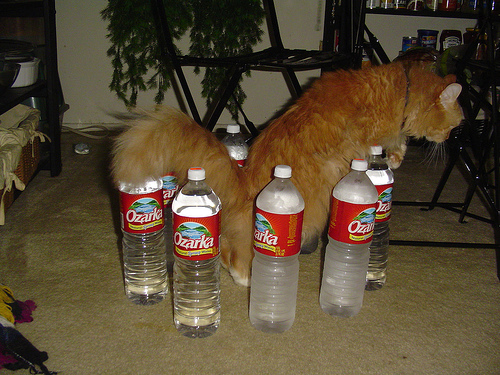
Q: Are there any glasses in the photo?
A: No, there are no glasses.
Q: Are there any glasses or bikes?
A: No, there are no glasses or bikes.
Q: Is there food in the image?
A: Yes, there is food.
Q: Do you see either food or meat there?
A: Yes, there is food.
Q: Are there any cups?
A: No, there are no cups.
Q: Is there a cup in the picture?
A: No, there are no cups.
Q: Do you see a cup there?
A: No, there are no cups.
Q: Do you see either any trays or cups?
A: No, there are no cups or trays.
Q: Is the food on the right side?
A: Yes, the food is on the right of the image.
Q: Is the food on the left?
A: No, the food is on the right of the image.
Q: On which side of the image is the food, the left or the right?
A: The food is on the right of the image.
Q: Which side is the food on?
A: The food is on the right of the image.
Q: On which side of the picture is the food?
A: The food is on the right of the image.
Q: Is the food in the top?
A: Yes, the food is in the top of the image.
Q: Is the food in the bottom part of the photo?
A: No, the food is in the top of the image.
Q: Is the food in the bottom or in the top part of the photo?
A: The food is in the top of the image.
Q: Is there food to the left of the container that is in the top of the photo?
A: Yes, there is food to the left of the container.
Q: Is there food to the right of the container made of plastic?
A: No, the food is to the left of the container.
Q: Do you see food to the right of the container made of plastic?
A: No, the food is to the left of the container.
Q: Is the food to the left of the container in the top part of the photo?
A: Yes, the food is to the left of the container.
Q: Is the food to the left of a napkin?
A: No, the food is to the left of the container.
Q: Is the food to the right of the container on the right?
A: No, the food is to the left of the container.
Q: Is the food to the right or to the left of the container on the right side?
A: The food is to the left of the container.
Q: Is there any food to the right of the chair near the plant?
A: Yes, there is food to the right of the chair.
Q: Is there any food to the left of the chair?
A: No, the food is to the right of the chair.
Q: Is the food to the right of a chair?
A: Yes, the food is to the right of a chair.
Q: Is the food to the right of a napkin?
A: No, the food is to the right of a chair.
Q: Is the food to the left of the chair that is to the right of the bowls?
A: No, the food is to the right of the chair.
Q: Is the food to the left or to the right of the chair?
A: The food is to the right of the chair.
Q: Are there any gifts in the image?
A: No, there are no gifts.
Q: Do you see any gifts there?
A: No, there are no gifts.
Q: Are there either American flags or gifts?
A: No, there are no gifts or American flags.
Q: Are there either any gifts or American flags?
A: No, there are no gifts or American flags.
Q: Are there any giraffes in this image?
A: No, there are no giraffes.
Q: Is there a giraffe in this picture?
A: No, there are no giraffes.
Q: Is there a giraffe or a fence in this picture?
A: No, there are no giraffes or fences.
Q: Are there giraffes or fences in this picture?
A: No, there are no giraffes or fences.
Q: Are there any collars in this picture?
A: Yes, there is a collar.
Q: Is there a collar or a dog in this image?
A: Yes, there is a collar.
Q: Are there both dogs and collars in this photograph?
A: No, there is a collar but no dogs.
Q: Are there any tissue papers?
A: No, there are no tissue papers.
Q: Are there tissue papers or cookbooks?
A: No, there are no tissue papers or cookbooks.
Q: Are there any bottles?
A: Yes, there is a bottle.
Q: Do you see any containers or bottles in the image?
A: Yes, there is a bottle.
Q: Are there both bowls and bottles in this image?
A: Yes, there are both a bottle and a bowl.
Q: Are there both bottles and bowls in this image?
A: Yes, there are both a bottle and a bowl.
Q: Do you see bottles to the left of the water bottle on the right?
A: Yes, there is a bottle to the left of the water bottle.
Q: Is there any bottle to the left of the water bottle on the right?
A: Yes, there is a bottle to the left of the water bottle.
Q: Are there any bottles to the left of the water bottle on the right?
A: Yes, there is a bottle to the left of the water bottle.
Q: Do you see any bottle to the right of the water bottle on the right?
A: No, the bottle is to the left of the water bottle.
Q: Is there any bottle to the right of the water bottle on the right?
A: No, the bottle is to the left of the water bottle.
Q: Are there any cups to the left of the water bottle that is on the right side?
A: No, there is a bottle to the left of the water bottle.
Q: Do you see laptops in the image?
A: No, there are no laptops.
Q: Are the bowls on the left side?
A: Yes, the bowls are on the left of the image.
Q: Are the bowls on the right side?
A: No, the bowls are on the left of the image.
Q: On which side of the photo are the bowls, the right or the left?
A: The bowls are on the left of the image.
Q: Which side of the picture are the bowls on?
A: The bowls are on the left of the image.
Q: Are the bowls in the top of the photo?
A: Yes, the bowls are in the top of the image.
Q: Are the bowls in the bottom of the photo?
A: No, the bowls are in the top of the image.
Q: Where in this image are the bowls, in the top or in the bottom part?
A: The bowls are in the top of the image.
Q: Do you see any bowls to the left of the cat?
A: Yes, there are bowls to the left of the cat.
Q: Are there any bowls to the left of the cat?
A: Yes, there are bowls to the left of the cat.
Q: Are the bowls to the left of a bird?
A: No, the bowls are to the left of the cat.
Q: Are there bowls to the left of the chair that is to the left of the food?
A: Yes, there are bowls to the left of the chair.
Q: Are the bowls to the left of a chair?
A: Yes, the bowls are to the left of a chair.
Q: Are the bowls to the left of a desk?
A: No, the bowls are to the left of a chair.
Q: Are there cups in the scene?
A: No, there are no cups.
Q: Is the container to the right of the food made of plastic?
A: Yes, the container is made of plastic.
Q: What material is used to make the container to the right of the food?
A: The container is made of plastic.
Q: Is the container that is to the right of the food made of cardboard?
A: No, the container is made of plastic.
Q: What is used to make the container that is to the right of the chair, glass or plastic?
A: The container is made of plastic.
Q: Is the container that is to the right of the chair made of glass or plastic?
A: The container is made of plastic.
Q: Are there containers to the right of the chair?
A: Yes, there is a container to the right of the chair.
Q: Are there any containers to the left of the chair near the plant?
A: No, the container is to the right of the chair.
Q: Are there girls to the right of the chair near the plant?
A: No, there is a container to the right of the chair.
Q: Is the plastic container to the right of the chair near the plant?
A: Yes, the container is to the right of the chair.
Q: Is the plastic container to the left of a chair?
A: No, the container is to the right of a chair.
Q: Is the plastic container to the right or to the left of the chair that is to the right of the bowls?
A: The container is to the right of the chair.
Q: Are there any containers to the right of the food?
A: Yes, there is a container to the right of the food.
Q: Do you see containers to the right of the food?
A: Yes, there is a container to the right of the food.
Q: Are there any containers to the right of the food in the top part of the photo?
A: Yes, there is a container to the right of the food.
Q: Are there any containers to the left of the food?
A: No, the container is to the right of the food.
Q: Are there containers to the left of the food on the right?
A: No, the container is to the right of the food.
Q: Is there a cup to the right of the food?
A: No, there is a container to the right of the food.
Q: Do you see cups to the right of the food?
A: No, there is a container to the right of the food.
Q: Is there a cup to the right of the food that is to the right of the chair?
A: No, there is a container to the right of the food.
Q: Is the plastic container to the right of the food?
A: Yes, the container is to the right of the food.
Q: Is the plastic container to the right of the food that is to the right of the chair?
A: Yes, the container is to the right of the food.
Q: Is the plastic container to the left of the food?
A: No, the container is to the right of the food.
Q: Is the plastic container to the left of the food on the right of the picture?
A: No, the container is to the right of the food.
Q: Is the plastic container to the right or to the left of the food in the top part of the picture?
A: The container is to the right of the food.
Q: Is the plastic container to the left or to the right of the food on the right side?
A: The container is to the right of the food.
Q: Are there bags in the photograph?
A: No, there are no bags.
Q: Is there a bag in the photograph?
A: No, there are no bags.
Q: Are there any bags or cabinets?
A: No, there are no bags or cabinets.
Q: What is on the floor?
A: The bottles are on the floor.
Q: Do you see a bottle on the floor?
A: Yes, there are bottles on the floor.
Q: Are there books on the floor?
A: No, there are bottles on the floor.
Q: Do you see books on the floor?
A: No, there are bottles on the floor.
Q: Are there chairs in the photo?
A: Yes, there is a chair.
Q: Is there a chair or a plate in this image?
A: Yes, there is a chair.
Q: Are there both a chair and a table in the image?
A: No, there is a chair but no tables.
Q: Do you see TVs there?
A: No, there are no tvs.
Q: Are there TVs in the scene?
A: No, there are no tvs.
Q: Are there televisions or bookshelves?
A: No, there are no televisions or bookshelves.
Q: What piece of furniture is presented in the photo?
A: The piece of furniture is a chair.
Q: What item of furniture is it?
A: The piece of furniture is a chair.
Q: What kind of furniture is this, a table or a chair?
A: This is a chair.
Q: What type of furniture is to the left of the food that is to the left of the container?
A: The piece of furniture is a chair.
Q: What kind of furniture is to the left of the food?
A: The piece of furniture is a chair.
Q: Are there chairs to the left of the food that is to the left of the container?
A: Yes, there is a chair to the left of the food.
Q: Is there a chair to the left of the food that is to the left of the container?
A: Yes, there is a chair to the left of the food.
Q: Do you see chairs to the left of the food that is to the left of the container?
A: Yes, there is a chair to the left of the food.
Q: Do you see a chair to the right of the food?
A: No, the chair is to the left of the food.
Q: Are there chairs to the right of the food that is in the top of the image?
A: No, the chair is to the left of the food.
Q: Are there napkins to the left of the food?
A: No, there is a chair to the left of the food.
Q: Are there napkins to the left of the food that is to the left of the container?
A: No, there is a chair to the left of the food.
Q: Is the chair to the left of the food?
A: Yes, the chair is to the left of the food.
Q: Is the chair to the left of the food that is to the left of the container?
A: Yes, the chair is to the left of the food.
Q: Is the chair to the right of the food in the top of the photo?
A: No, the chair is to the left of the food.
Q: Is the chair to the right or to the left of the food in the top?
A: The chair is to the left of the food.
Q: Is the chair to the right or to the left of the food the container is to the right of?
A: The chair is to the left of the food.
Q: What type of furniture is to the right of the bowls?
A: The piece of furniture is a chair.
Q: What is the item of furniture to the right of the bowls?
A: The piece of furniture is a chair.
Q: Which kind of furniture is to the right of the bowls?
A: The piece of furniture is a chair.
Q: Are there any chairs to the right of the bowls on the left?
A: Yes, there is a chair to the right of the bowls.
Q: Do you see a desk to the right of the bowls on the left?
A: No, there is a chair to the right of the bowls.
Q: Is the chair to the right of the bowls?
A: Yes, the chair is to the right of the bowls.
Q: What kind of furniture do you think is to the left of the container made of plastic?
A: The piece of furniture is a chair.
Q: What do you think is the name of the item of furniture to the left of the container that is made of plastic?
A: The piece of furniture is a chair.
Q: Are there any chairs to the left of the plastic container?
A: Yes, there is a chair to the left of the container.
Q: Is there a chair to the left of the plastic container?
A: Yes, there is a chair to the left of the container.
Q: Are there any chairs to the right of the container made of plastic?
A: No, the chair is to the left of the container.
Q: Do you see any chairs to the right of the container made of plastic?
A: No, the chair is to the left of the container.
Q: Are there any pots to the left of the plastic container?
A: No, there is a chair to the left of the container.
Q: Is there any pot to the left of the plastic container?
A: No, there is a chair to the left of the container.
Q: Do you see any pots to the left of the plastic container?
A: No, there is a chair to the left of the container.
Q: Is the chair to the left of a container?
A: Yes, the chair is to the left of a container.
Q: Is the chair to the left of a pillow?
A: No, the chair is to the left of a container.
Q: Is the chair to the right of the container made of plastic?
A: No, the chair is to the left of the container.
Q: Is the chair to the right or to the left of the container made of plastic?
A: The chair is to the left of the container.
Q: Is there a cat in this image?
A: Yes, there is a cat.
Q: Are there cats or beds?
A: Yes, there is a cat.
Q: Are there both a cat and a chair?
A: Yes, there are both a cat and a chair.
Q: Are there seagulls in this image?
A: No, there are no seagulls.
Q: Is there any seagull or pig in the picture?
A: No, there are no seagulls or pigs.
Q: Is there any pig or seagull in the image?
A: No, there are no seagulls or pigs.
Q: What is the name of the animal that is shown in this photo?
A: The animal is a cat.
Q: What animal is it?
A: The animal is a cat.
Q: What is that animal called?
A: This is a cat.